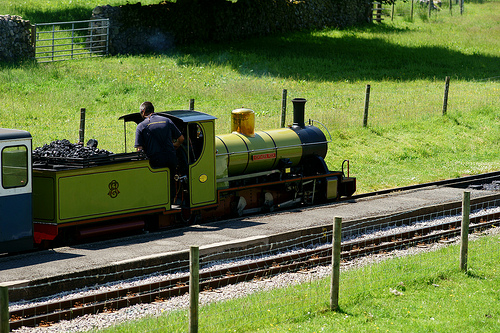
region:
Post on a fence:
[180, 238, 223, 332]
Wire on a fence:
[206, 236, 347, 329]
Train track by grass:
[122, 242, 284, 307]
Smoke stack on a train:
[278, 84, 314, 117]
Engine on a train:
[203, 103, 350, 217]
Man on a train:
[113, 93, 202, 208]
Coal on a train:
[39, 121, 103, 181]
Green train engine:
[28, 102, 213, 249]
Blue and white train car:
[5, 125, 62, 254]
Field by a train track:
[110, 21, 398, 195]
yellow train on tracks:
[4, 14, 456, 305]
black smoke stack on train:
[247, 92, 339, 127]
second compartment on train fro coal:
[35, 108, 217, 252]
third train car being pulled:
[0, 128, 40, 230]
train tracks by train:
[81, 207, 413, 329]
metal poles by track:
[324, 208, 381, 300]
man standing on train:
[130, 90, 194, 194]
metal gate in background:
[11, 5, 145, 117]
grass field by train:
[37, 38, 368, 138]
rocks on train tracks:
[148, 238, 323, 330]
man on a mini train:
[131, 88, 189, 225]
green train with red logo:
[219, 125, 334, 196]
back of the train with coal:
[22, 133, 128, 228]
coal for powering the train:
[37, 129, 97, 169]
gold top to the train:
[223, 94, 273, 161]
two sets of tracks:
[369, 186, 434, 250]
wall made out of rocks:
[140, 9, 223, 49]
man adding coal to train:
[124, 95, 189, 247]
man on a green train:
[25, 54, 410, 224]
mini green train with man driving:
[21, 96, 361, 220]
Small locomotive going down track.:
[0, 91, 356, 258]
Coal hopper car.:
[19, 132, 172, 247]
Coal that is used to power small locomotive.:
[18, 132, 115, 172]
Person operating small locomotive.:
[132, 97, 197, 213]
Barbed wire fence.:
[0, 185, 499, 331]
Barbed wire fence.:
[0, 67, 498, 189]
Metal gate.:
[30, 17, 115, 67]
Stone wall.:
[89, 1, 379, 61]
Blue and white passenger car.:
[0, 118, 36, 260]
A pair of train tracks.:
[0, 165, 499, 331]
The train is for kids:
[202, 85, 377, 220]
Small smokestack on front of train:
[280, 80, 319, 122]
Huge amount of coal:
[32, 115, 122, 192]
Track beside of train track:
[347, 198, 487, 270]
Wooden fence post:
[321, 204, 351, 327]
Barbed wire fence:
[192, 226, 356, 299]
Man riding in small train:
[129, 82, 186, 183]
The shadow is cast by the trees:
[312, 24, 498, 78]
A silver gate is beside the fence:
[28, 21, 113, 58]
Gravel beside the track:
[328, 202, 361, 216]